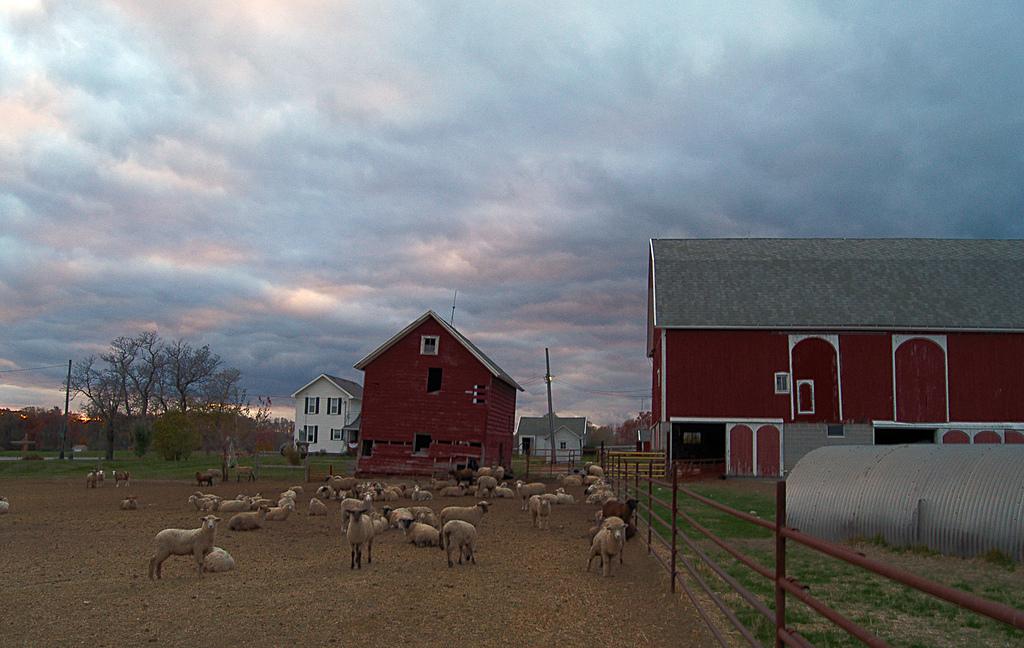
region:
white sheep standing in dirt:
[141, 510, 212, 565]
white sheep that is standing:
[577, 513, 622, 574]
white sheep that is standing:
[441, 510, 473, 564]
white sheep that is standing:
[342, 513, 374, 567]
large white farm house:
[295, 365, 359, 449]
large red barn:
[358, 305, 513, 476]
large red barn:
[643, 232, 1018, 468]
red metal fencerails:
[592, 450, 1020, 635]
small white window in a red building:
[419, 334, 440, 355]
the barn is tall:
[355, 307, 524, 482]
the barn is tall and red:
[355, 307, 524, 484]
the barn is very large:
[636, 236, 1020, 480]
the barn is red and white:
[642, 236, 1019, 481]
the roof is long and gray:
[640, 237, 1017, 330]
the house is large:
[289, 373, 363, 456]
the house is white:
[291, 372, 361, 453]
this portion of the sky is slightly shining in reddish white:
[247, 275, 350, 310]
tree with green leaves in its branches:
[152, 404, 195, 463]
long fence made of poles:
[584, 450, 1005, 644]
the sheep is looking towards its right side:
[146, 506, 220, 582]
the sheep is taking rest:
[114, 485, 143, 509]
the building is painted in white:
[290, 374, 363, 450]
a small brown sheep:
[581, 511, 635, 578]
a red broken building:
[339, 308, 524, 487]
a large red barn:
[630, 239, 1022, 487]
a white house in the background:
[279, 368, 369, 463]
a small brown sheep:
[146, 510, 219, 586]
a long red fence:
[579, 439, 1022, 642]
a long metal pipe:
[758, 432, 1022, 568]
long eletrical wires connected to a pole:
[4, 357, 188, 390]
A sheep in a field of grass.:
[144, 512, 225, 576]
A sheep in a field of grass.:
[436, 513, 475, 555]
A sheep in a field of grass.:
[591, 514, 620, 566]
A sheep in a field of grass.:
[438, 501, 490, 525]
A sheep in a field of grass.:
[381, 485, 401, 505]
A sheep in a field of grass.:
[230, 506, 272, 523]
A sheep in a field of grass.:
[113, 495, 139, 511]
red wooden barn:
[325, 298, 531, 488]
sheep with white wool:
[137, 509, 233, 582]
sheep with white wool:
[324, 490, 385, 576]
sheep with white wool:
[579, 510, 637, 588]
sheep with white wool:
[438, 515, 486, 574]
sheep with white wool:
[431, 491, 498, 533]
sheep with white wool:
[223, 494, 278, 534]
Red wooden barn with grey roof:
[614, 197, 1022, 493]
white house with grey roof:
[279, 346, 368, 467]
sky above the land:
[176, 54, 537, 271]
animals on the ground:
[133, 417, 645, 605]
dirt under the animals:
[458, 543, 579, 633]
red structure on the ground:
[303, 269, 579, 485]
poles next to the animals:
[638, 462, 880, 622]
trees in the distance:
[28, 329, 272, 447]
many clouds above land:
[123, 100, 556, 287]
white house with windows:
[275, 377, 355, 460]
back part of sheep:
[129, 521, 191, 591]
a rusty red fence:
[593, 442, 1023, 640]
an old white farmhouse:
[286, 372, 360, 458]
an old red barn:
[355, 309, 523, 468]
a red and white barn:
[643, 232, 1023, 477]